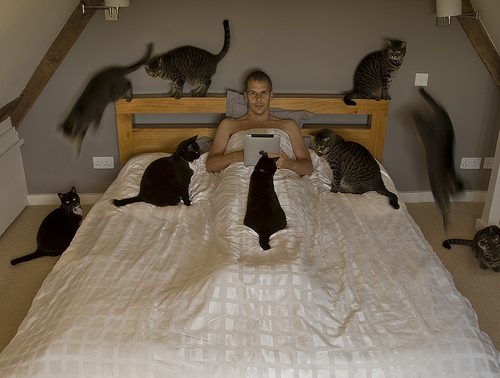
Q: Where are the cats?
A: Bedroom.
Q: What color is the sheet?
A: White.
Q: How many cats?
A: 9.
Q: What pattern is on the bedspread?
A: Squares.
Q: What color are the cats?
A: Brown, black and white.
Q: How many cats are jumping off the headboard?
A: Two.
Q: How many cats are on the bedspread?
A: Three.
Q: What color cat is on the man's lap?
A: Black.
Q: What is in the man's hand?
A: Tablet.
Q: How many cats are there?
A: Nine.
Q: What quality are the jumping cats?
A: Blurry.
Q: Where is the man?
A: In bed.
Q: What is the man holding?
A: An iPad.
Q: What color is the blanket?
A: White.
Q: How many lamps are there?
A: Two.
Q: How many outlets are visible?
A: Three.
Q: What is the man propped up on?
A: A pillow.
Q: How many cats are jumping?
A: Two.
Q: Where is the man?
A: In bed.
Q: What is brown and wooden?
A: Headboard.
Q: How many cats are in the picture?
A: 9.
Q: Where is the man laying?
A: In bed.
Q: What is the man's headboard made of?
A: Wood.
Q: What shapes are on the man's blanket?
A: Squares.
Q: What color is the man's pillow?
A: Gray.